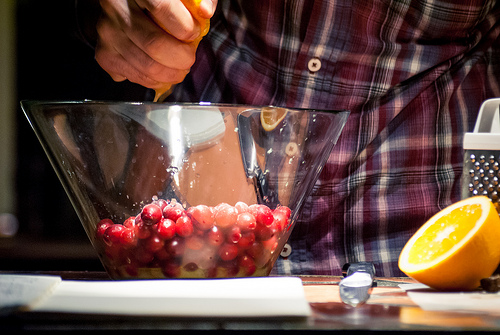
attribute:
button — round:
[305, 54, 321, 73]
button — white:
[306, 50, 325, 79]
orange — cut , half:
[389, 189, 498, 281]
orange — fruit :
[388, 180, 498, 286]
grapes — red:
[83, 190, 286, 280]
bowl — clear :
[4, 92, 357, 302]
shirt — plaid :
[69, 0, 493, 273]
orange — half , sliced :
[390, 186, 496, 289]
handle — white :
[453, 85, 498, 155]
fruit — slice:
[115, 3, 269, 130]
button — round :
[300, 49, 324, 76]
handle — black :
[341, 253, 385, 283]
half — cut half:
[392, 185, 498, 284]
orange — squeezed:
[145, 3, 220, 114]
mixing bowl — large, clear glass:
[6, 73, 335, 311]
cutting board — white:
[38, 259, 318, 333]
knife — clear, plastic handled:
[310, 252, 403, 325]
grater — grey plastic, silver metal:
[431, 79, 494, 289]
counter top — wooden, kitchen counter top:
[20, 267, 498, 333]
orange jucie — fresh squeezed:
[138, 13, 224, 97]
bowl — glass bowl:
[2, 62, 354, 292]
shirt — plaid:
[214, 14, 484, 288]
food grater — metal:
[451, 100, 499, 240]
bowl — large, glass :
[26, 74, 340, 307]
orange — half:
[388, 196, 499, 295]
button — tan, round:
[298, 53, 328, 81]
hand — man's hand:
[84, 0, 228, 99]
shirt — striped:
[193, 8, 400, 216]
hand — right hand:
[58, 3, 199, 87]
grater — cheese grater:
[441, 98, 500, 251]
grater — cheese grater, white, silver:
[446, 78, 498, 228]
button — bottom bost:
[276, 240, 298, 264]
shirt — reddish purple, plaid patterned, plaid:
[197, 8, 477, 275]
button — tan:
[274, 130, 312, 175]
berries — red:
[99, 180, 270, 275]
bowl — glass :
[9, 77, 357, 297]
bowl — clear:
[17, 104, 375, 298]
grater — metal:
[445, 85, 498, 252]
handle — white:
[457, 115, 497, 152]